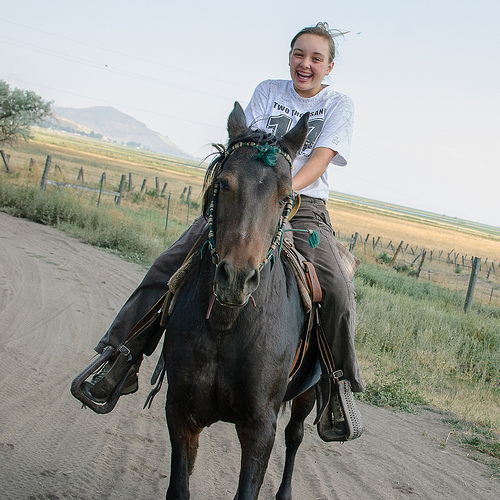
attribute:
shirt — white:
[243, 81, 353, 204]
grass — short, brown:
[0, 125, 497, 476]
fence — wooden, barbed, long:
[1, 148, 497, 317]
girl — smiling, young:
[76, 22, 366, 435]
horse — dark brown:
[142, 102, 356, 499]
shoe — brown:
[82, 359, 138, 404]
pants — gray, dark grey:
[93, 194, 366, 393]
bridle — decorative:
[197, 138, 318, 276]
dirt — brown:
[0, 209, 499, 497]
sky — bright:
[1, 1, 499, 228]